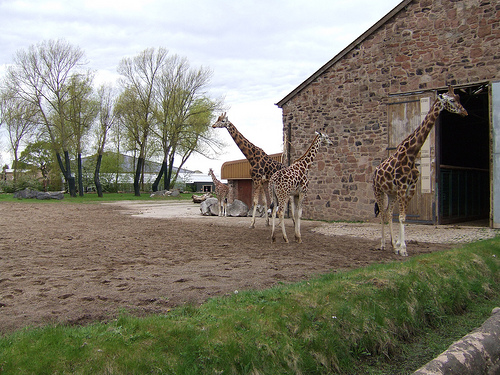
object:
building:
[272, 4, 500, 227]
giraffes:
[365, 83, 470, 260]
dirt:
[0, 202, 475, 330]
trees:
[0, 36, 85, 199]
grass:
[9, 185, 138, 201]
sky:
[0, 2, 379, 140]